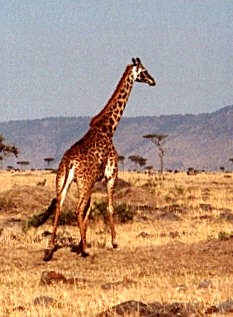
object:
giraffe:
[30, 57, 156, 263]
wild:
[0, 0, 233, 317]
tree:
[141, 133, 170, 173]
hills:
[0, 101, 232, 173]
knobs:
[134, 56, 141, 65]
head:
[127, 56, 157, 88]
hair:
[30, 195, 59, 225]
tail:
[28, 161, 77, 230]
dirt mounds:
[0, 175, 155, 221]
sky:
[0, 1, 231, 122]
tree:
[43, 157, 54, 168]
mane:
[89, 63, 131, 125]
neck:
[97, 74, 134, 136]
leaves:
[152, 133, 156, 137]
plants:
[0, 166, 233, 316]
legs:
[76, 182, 90, 255]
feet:
[79, 246, 94, 256]